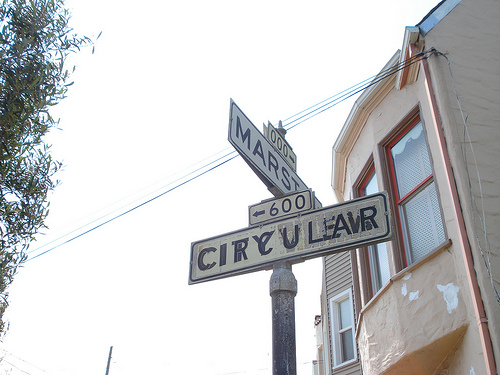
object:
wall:
[352, 246, 486, 373]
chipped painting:
[468, 363, 474, 373]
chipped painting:
[436, 279, 463, 316]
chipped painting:
[407, 285, 421, 303]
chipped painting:
[400, 283, 409, 297]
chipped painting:
[403, 272, 415, 282]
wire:
[0, 32, 450, 280]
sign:
[188, 193, 392, 285]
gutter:
[394, 26, 424, 88]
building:
[309, 0, 498, 374]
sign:
[224, 96, 326, 211]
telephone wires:
[12, 47, 449, 272]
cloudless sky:
[2, 0, 456, 372]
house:
[267, 32, 494, 374]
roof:
[331, 24, 423, 195]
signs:
[226, 104, 331, 209]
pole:
[269, 265, 297, 374]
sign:
[160, 106, 353, 280]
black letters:
[197, 245, 217, 270]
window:
[325, 288, 352, 371]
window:
[375, 112, 450, 261]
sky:
[108, 32, 197, 94]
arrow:
[250, 209, 265, 216]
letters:
[233, 115, 253, 148]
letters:
[216, 241, 229, 266]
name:
[234, 114, 302, 194]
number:
[268, 127, 280, 142]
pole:
[104, 344, 114, 374]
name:
[197, 203, 379, 270]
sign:
[247, 187, 314, 227]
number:
[268, 202, 281, 216]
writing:
[251, 231, 278, 257]